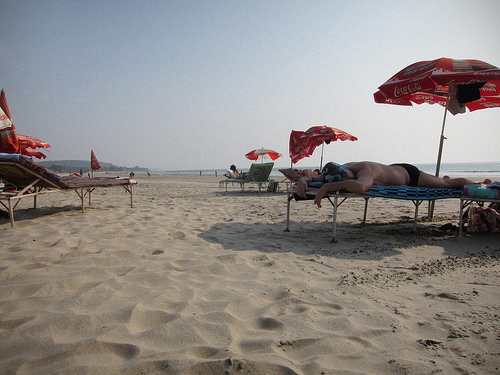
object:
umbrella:
[373, 57, 500, 116]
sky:
[1, 0, 500, 168]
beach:
[0, 171, 499, 375]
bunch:
[115, 298, 146, 322]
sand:
[374, 333, 416, 351]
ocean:
[134, 161, 500, 176]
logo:
[393, 82, 422, 98]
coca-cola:
[394, 83, 422, 98]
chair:
[0, 154, 138, 228]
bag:
[462, 205, 498, 237]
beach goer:
[146, 171, 151, 178]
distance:
[69, 162, 223, 181]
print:
[137, 306, 175, 330]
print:
[110, 264, 135, 278]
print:
[256, 316, 283, 330]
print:
[174, 258, 209, 265]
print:
[174, 272, 208, 287]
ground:
[0, 172, 500, 375]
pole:
[430, 85, 451, 219]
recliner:
[222, 164, 249, 179]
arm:
[322, 176, 373, 195]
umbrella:
[90, 150, 102, 171]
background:
[0, 47, 500, 177]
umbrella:
[245, 149, 283, 162]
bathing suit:
[389, 162, 422, 187]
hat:
[320, 161, 349, 184]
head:
[321, 161, 357, 182]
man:
[295, 161, 493, 208]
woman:
[293, 168, 321, 177]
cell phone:
[300, 167, 304, 172]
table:
[457, 196, 500, 240]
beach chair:
[219, 161, 275, 192]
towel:
[364, 184, 465, 201]